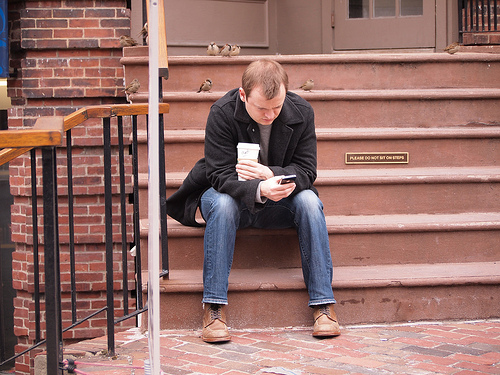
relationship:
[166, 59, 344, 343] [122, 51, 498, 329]
man sitting on stairs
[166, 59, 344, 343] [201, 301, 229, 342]
man wearing shoe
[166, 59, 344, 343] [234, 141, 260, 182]
man holding cup of coffee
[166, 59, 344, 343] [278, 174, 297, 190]
man holding cell phone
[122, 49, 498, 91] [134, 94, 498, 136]
step next to step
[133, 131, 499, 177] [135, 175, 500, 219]
step next to step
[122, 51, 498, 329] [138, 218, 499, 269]
stairs have step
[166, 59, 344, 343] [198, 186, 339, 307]
man wearing jeans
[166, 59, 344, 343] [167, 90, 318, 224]
man wearing jacket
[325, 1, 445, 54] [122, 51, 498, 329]
door at top of stairs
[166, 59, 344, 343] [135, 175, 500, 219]
man sitting on step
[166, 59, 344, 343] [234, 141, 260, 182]
man drinking cup of coffee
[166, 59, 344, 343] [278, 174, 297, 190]
man looking at cell phone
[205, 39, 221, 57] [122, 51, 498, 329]
bird standing on stairs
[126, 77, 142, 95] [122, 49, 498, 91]
bird standing on step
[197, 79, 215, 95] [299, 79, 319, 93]
bird next to bird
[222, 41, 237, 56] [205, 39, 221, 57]
bird next to bird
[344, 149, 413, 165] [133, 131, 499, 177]
outdoor sign attached to step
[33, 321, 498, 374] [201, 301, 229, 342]
ground under shoe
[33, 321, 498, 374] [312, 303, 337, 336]
ground under shoe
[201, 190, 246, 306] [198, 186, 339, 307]
leg wearing jeans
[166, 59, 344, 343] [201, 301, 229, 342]
man has shoe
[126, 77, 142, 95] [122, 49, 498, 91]
bird sitting on step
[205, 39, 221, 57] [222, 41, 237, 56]
bird next to bird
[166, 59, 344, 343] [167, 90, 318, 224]
man has jacket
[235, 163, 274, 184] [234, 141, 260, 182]
hand holding cup of coffee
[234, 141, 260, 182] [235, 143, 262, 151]
cup of coffee has lid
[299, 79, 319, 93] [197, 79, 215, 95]
bird next to bird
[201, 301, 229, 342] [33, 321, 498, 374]
shoe on ground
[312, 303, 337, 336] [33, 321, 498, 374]
shoe resting on ground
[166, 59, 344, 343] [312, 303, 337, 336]
man has shoe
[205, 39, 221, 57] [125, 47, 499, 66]
bird sitting on top step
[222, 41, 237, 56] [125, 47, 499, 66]
bird sitting on top step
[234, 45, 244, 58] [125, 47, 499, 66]
bird sitting on top step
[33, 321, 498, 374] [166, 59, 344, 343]
ground by man